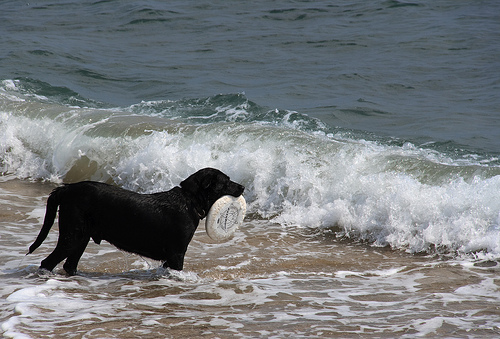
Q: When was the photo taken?
A: Daytime.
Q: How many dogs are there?
A: One.